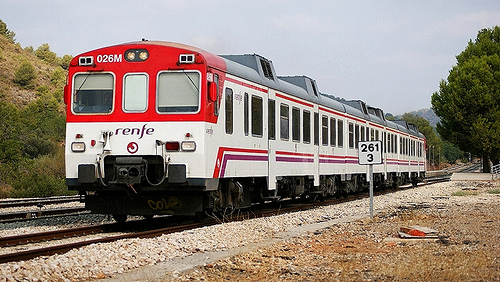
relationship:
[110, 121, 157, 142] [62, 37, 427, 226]
word "renfe" on train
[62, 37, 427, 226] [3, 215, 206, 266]
train on track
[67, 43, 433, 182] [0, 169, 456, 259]
train on track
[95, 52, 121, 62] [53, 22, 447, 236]
print on train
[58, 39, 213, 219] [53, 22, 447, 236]
front of train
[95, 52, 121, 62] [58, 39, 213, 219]
print on front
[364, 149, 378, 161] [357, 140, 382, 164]
3 printed on sign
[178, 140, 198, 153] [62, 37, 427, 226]
headlight on train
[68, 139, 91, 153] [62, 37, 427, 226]
headlight on train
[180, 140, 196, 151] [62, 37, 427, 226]
headlight of a train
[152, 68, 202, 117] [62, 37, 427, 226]
window of a train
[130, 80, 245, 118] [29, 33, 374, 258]
window of a train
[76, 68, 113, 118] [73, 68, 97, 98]
windshield has a wiper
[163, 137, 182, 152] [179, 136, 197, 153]
red light next to white light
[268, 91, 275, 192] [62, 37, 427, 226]
door on train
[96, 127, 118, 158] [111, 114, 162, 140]
horn next to logo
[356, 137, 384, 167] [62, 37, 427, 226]
sign next to train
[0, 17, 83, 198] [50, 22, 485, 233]
hill next to train